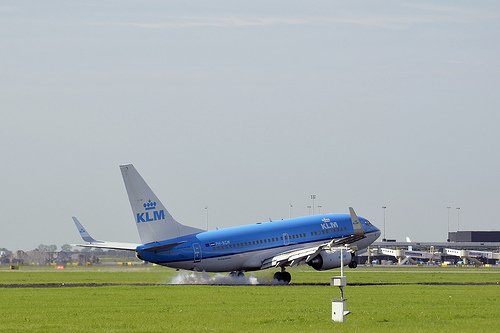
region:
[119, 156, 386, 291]
blue and white plane on green grass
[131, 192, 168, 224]
crown logo with KLM on tail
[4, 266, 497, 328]
field covered in green grass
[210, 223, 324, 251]
Lots of windows on plane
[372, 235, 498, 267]
vehicles in distance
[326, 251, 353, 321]
white object in green grass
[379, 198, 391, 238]
light poles in distance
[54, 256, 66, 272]
orange object in distance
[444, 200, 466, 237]
Two light poles together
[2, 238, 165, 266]
Trees in the distance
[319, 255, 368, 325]
Light on white box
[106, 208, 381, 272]
Blue and white airplane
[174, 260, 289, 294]
Smoke coming from bottom of plane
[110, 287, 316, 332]
Manicured green grass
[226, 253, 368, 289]
Plane with landing gear down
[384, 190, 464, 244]
Lamp posts above airport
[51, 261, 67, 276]
Red sign on ground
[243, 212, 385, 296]
Blue and white plane taking off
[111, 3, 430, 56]
Wispy white clouds in sky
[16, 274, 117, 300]
Airport runway surrounded by grass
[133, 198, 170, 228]
blue letters on airplane tail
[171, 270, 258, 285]
smoke for tires while landing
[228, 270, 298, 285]
landing gears in down position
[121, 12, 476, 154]
very few white clouds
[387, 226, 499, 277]
airport terminal in the distance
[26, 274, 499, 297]
airplane landing strip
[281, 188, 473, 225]
lights at the terminal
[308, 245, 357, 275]
airplane motor under wing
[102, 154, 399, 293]
blue and white airplane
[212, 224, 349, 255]
windows on side of airplane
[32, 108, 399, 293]
A white and blue airplane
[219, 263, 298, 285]
The wheels on the airplane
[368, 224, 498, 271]
an airport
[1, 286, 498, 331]
A large grassy field in the runway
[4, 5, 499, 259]
A clear blue sky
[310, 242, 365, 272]
engine on the right wing of the plane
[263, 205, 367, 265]
The right wing of the plane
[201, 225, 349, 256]
passenger windows on the plane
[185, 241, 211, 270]
rear door on the plane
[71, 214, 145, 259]
left wing of the plane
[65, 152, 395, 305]
plane on airport runway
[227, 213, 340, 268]
blue and white body of plane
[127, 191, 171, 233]
logo on white tail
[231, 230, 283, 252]
windows on side of plane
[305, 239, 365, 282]
jet engine under wing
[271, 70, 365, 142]
pale blue of daytime sky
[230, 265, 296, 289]
wheels of landing gear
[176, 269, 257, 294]
white cloud over runway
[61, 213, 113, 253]
upturned tip of wing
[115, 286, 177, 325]
green grass along runway